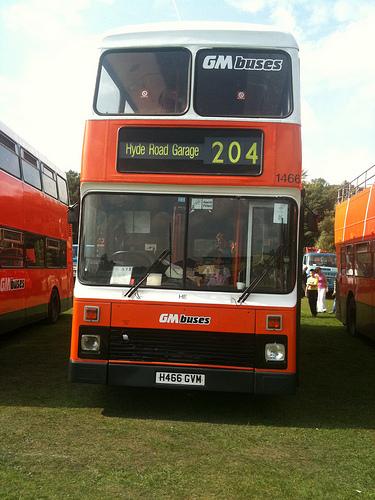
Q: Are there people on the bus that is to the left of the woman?
A: Yes, there is a person on the bus.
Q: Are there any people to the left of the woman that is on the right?
A: Yes, there is a person to the left of the woman.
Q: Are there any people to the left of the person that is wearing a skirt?
A: Yes, there is a person to the left of the woman.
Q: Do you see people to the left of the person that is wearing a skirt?
A: Yes, there is a person to the left of the woman.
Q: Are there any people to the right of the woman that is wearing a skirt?
A: No, the person is to the left of the woman.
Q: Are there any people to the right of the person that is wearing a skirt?
A: No, the person is to the left of the woman.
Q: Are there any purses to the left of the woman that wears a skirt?
A: No, there is a person to the left of the woman.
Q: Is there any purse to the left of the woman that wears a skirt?
A: No, there is a person to the left of the woman.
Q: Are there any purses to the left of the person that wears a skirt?
A: No, there is a person to the left of the woman.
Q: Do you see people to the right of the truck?
A: No, the person is to the left of the truck.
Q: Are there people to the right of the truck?
A: No, the person is to the left of the truck.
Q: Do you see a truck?
A: Yes, there is a truck.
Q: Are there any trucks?
A: Yes, there is a truck.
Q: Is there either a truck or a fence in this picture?
A: Yes, there is a truck.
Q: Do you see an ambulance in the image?
A: No, there are no ambulances.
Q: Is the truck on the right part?
A: Yes, the truck is on the right of the image.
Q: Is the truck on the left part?
A: No, the truck is on the right of the image.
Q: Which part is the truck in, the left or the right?
A: The truck is on the right of the image.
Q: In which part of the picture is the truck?
A: The truck is on the right of the image.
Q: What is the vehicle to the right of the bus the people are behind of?
A: The vehicle is a truck.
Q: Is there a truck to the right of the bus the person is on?
A: Yes, there is a truck to the right of the bus.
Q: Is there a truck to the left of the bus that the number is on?
A: No, the truck is to the right of the bus.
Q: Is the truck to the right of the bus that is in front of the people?
A: Yes, the truck is to the right of the bus.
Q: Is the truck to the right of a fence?
A: No, the truck is to the right of the bus.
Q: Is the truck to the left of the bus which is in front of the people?
A: No, the truck is to the right of the bus.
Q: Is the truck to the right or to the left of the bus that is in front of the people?
A: The truck is to the right of the bus.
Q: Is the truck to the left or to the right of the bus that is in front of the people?
A: The truck is to the right of the bus.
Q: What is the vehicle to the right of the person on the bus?
A: The vehicle is a truck.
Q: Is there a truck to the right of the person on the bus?
A: Yes, there is a truck to the right of the person.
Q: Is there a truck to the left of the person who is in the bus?
A: No, the truck is to the right of the person.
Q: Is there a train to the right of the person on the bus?
A: No, there is a truck to the right of the person.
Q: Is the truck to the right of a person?
A: Yes, the truck is to the right of a person.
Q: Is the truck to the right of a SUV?
A: No, the truck is to the right of a person.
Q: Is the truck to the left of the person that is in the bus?
A: No, the truck is to the right of the person.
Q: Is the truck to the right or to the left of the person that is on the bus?
A: The truck is to the right of the person.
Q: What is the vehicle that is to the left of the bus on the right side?
A: The vehicle is a truck.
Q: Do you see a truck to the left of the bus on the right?
A: Yes, there is a truck to the left of the bus.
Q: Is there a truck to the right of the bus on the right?
A: No, the truck is to the left of the bus.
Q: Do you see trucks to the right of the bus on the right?
A: No, the truck is to the left of the bus.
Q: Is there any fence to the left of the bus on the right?
A: No, there is a truck to the left of the bus.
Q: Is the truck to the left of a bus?
A: Yes, the truck is to the left of a bus.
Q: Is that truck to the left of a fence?
A: No, the truck is to the left of a bus.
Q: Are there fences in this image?
A: No, there are no fences.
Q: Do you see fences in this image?
A: No, there are no fences.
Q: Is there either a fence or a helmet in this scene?
A: No, there are no fences or helmets.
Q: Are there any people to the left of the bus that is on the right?
A: Yes, there are people to the left of the bus.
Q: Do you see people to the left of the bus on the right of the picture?
A: Yes, there are people to the left of the bus.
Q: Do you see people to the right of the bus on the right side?
A: No, the people are to the left of the bus.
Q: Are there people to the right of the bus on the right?
A: No, the people are to the left of the bus.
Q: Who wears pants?
A: The people wear pants.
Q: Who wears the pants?
A: The people wear pants.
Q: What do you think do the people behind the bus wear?
A: The people wear pants.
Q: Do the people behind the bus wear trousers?
A: Yes, the people wear trousers.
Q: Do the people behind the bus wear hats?
A: No, the people wear trousers.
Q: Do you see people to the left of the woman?
A: Yes, there are people to the left of the woman.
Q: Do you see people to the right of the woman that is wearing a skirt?
A: No, the people are to the left of the woman.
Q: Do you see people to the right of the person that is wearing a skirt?
A: No, the people are to the left of the woman.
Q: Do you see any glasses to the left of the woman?
A: No, there are people to the left of the woman.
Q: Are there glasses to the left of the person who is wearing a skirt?
A: No, there are people to the left of the woman.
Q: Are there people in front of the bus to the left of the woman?
A: No, the people are behind the bus.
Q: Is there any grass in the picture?
A: Yes, there is grass.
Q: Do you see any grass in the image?
A: Yes, there is grass.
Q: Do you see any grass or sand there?
A: Yes, there is grass.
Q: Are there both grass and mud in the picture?
A: No, there is grass but no mud.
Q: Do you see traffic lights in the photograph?
A: No, there are no traffic lights.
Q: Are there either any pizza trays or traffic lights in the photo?
A: No, there are no traffic lights or pizza trays.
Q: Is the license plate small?
A: Yes, the license plate is small.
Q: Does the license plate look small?
A: Yes, the license plate is small.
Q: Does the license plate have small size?
A: Yes, the license plate is small.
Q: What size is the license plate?
A: The license plate is small.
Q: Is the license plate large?
A: No, the license plate is small.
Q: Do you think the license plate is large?
A: No, the license plate is small.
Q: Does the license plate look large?
A: No, the license plate is small.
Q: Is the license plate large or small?
A: The license plate is small.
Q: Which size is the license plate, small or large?
A: The license plate is small.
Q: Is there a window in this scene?
A: Yes, there is a window.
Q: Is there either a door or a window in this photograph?
A: Yes, there is a window.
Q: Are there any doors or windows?
A: Yes, there is a window.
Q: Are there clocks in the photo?
A: No, there are no clocks.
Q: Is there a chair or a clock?
A: No, there are no clocks or chairs.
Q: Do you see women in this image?
A: Yes, there is a woman.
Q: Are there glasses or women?
A: Yes, there is a woman.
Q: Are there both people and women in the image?
A: Yes, there are both a woman and people.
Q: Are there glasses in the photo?
A: No, there are no glasses.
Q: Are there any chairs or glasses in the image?
A: No, there are no glasses or chairs.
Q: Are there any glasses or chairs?
A: No, there are no glasses or chairs.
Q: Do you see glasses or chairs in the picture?
A: No, there are no glasses or chairs.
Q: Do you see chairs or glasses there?
A: No, there are no glasses or chairs.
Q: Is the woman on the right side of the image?
A: Yes, the woman is on the right of the image.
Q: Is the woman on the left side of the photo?
A: No, the woman is on the right of the image.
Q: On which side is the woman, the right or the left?
A: The woman is on the right of the image.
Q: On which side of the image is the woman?
A: The woman is on the right of the image.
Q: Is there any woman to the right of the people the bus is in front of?
A: Yes, there is a woman to the right of the people.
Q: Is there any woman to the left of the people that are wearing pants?
A: No, the woman is to the right of the people.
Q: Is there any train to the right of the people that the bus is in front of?
A: No, there is a woman to the right of the people.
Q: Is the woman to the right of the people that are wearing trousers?
A: Yes, the woman is to the right of the people.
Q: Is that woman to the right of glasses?
A: No, the woman is to the right of the people.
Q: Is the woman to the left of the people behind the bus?
A: No, the woman is to the right of the people.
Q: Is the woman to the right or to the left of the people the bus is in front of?
A: The woman is to the right of the people.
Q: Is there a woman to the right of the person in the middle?
A: Yes, there is a woman to the right of the person.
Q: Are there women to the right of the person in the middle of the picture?
A: Yes, there is a woman to the right of the person.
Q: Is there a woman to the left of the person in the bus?
A: No, the woman is to the right of the person.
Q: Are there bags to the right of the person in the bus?
A: No, there is a woman to the right of the person.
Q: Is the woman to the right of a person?
A: Yes, the woman is to the right of a person.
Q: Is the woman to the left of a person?
A: No, the woman is to the right of a person.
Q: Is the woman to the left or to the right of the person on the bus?
A: The woman is to the right of the person.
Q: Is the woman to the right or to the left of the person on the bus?
A: The woman is to the right of the person.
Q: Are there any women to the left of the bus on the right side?
A: Yes, there is a woman to the left of the bus.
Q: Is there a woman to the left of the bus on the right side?
A: Yes, there is a woman to the left of the bus.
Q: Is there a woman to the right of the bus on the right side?
A: No, the woman is to the left of the bus.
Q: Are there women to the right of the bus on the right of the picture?
A: No, the woman is to the left of the bus.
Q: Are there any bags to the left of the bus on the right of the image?
A: No, there is a woman to the left of the bus.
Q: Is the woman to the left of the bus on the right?
A: Yes, the woman is to the left of the bus.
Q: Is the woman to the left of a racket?
A: No, the woman is to the left of the bus.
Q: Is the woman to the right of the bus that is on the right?
A: No, the woman is to the left of the bus.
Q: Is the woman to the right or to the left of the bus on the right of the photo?
A: The woman is to the left of the bus.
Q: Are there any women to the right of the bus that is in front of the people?
A: Yes, there is a woman to the right of the bus.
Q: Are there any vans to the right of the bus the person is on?
A: No, there is a woman to the right of the bus.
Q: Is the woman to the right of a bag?
A: No, the woman is to the right of the bus.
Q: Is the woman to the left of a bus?
A: No, the woman is to the right of a bus.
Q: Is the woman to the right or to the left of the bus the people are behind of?
A: The woman is to the right of the bus.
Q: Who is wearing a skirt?
A: The woman is wearing a skirt.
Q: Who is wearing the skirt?
A: The woman is wearing a skirt.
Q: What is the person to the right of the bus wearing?
A: The woman is wearing a skirt.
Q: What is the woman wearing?
A: The woman is wearing a skirt.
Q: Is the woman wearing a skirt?
A: Yes, the woman is wearing a skirt.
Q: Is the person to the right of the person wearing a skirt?
A: Yes, the woman is wearing a skirt.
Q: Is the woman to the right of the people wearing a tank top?
A: No, the woman is wearing a skirt.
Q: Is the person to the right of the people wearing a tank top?
A: No, the woman is wearing a skirt.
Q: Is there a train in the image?
A: No, there are no trains.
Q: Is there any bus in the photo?
A: Yes, there is a bus.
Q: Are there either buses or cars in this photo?
A: Yes, there is a bus.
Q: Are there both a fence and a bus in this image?
A: No, there is a bus but no fences.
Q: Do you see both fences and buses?
A: No, there is a bus but no fences.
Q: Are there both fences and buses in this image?
A: No, there is a bus but no fences.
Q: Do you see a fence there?
A: No, there are no fences.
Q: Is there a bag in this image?
A: No, there are no bags.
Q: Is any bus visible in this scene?
A: Yes, there is a bus.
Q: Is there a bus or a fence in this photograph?
A: Yes, there is a bus.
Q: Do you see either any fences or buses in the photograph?
A: Yes, there is a bus.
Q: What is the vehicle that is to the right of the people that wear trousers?
A: The vehicle is a bus.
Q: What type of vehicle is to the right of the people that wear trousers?
A: The vehicle is a bus.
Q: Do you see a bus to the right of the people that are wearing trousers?
A: Yes, there is a bus to the right of the people.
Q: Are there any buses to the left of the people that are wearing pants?
A: No, the bus is to the right of the people.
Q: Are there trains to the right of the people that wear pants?
A: No, there is a bus to the right of the people.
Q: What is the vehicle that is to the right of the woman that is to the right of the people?
A: The vehicle is a bus.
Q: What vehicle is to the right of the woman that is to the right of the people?
A: The vehicle is a bus.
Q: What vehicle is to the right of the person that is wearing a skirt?
A: The vehicle is a bus.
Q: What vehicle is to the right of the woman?
A: The vehicle is a bus.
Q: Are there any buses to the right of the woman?
A: Yes, there is a bus to the right of the woman.